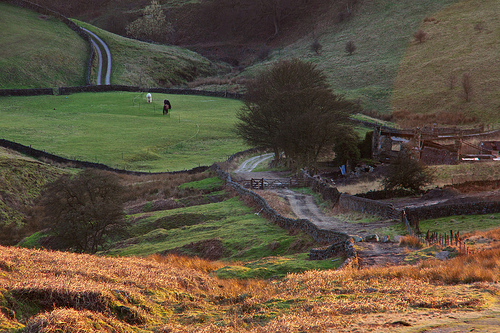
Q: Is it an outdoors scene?
A: Yes, it is outdoors.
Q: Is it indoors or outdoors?
A: It is outdoors.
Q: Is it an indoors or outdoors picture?
A: It is outdoors.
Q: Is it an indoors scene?
A: No, it is outdoors.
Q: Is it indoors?
A: No, it is outdoors.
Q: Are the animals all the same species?
A: Yes, all the animals are horses.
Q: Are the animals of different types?
A: No, all the animals are horses.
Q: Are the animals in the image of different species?
A: No, all the animals are horses.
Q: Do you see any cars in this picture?
A: No, there are no cars.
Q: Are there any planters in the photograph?
A: No, there are no planters.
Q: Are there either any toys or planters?
A: No, there are no planters or toys.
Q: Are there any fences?
A: Yes, there is a fence.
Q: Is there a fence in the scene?
A: Yes, there is a fence.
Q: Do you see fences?
A: Yes, there is a fence.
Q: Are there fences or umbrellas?
A: Yes, there is a fence.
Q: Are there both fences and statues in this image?
A: No, there is a fence but no statues.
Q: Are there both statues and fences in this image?
A: No, there is a fence but no statues.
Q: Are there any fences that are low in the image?
A: Yes, there is a low fence.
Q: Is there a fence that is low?
A: Yes, there is a fence that is low.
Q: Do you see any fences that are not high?
A: Yes, there is a low fence.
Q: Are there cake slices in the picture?
A: No, there are no cake slices.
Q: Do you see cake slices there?
A: No, there are no cake slices.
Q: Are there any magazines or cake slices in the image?
A: No, there are no cake slices or magazines.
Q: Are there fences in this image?
A: Yes, there is a fence.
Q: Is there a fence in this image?
A: Yes, there is a fence.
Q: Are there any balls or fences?
A: Yes, there is a fence.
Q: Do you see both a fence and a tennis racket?
A: No, there is a fence but no rackets.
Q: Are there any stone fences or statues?
A: Yes, there is a stone fence.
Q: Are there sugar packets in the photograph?
A: No, there are no sugar packets.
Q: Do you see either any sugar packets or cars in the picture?
A: No, there are no sugar packets or cars.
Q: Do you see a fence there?
A: Yes, there is a fence.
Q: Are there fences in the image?
A: Yes, there is a fence.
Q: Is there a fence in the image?
A: Yes, there is a fence.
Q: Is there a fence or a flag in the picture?
A: Yes, there is a fence.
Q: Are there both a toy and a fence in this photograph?
A: No, there is a fence but no toys.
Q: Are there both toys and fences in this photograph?
A: No, there is a fence but no toys.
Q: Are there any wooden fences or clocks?
A: Yes, there is a wood fence.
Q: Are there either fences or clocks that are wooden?
A: Yes, the fence is wooden.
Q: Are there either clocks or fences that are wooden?
A: Yes, the fence is wooden.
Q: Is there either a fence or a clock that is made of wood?
A: Yes, the fence is made of wood.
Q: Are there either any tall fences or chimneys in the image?
A: Yes, there is a tall fence.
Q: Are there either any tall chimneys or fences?
A: Yes, there is a tall fence.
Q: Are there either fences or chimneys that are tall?
A: Yes, the fence is tall.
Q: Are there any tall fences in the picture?
A: Yes, there is a tall fence.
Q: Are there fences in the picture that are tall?
A: Yes, there is a fence that is tall.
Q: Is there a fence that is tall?
A: Yes, there is a fence that is tall.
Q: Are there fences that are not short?
A: Yes, there is a tall fence.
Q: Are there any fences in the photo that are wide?
A: Yes, there is a wide fence.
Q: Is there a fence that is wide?
A: Yes, there is a fence that is wide.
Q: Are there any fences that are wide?
A: Yes, there is a fence that is wide.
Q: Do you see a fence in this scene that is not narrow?
A: Yes, there is a wide fence.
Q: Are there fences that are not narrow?
A: Yes, there is a wide fence.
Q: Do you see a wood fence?
A: Yes, there is a wood fence.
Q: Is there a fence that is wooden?
A: Yes, there is a fence that is wooden.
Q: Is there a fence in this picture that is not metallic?
A: Yes, there is a wooden fence.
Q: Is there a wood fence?
A: Yes, there is a fence that is made of wood.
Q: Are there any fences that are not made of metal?
A: Yes, there is a fence that is made of wood.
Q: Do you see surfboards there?
A: No, there are no surfboards.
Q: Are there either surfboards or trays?
A: No, there are no surfboards or trays.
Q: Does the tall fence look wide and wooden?
A: Yes, the fence is wide and wooden.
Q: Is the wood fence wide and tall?
A: Yes, the fence is wide and tall.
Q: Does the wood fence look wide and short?
A: No, the fence is wide but tall.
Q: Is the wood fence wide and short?
A: No, the fence is wide but tall.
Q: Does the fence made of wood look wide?
A: Yes, the fence is wide.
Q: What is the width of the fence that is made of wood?
A: The fence is wide.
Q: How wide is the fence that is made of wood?
A: The fence is wide.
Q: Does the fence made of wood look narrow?
A: No, the fence is wide.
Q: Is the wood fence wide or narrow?
A: The fence is wide.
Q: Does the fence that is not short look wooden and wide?
A: Yes, the fence is wooden and wide.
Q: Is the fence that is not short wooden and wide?
A: Yes, the fence is wooden and wide.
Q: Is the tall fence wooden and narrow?
A: No, the fence is wooden but wide.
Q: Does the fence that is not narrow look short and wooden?
A: No, the fence is wooden but tall.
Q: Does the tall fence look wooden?
A: Yes, the fence is wooden.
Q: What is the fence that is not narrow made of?
A: The fence is made of wood.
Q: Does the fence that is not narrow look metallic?
A: No, the fence is wooden.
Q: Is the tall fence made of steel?
A: No, the fence is made of wood.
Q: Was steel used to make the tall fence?
A: No, the fence is made of wood.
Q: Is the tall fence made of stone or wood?
A: The fence is made of wood.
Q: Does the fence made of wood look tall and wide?
A: Yes, the fence is tall and wide.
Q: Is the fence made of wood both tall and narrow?
A: No, the fence is tall but wide.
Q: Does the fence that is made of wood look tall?
A: Yes, the fence is tall.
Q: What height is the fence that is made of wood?
A: The fence is tall.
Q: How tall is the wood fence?
A: The fence is tall.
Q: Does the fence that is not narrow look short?
A: No, the fence is tall.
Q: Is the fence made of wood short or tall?
A: The fence is tall.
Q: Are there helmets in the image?
A: No, there are no helmets.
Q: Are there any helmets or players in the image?
A: No, there are no helmets or players.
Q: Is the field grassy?
A: Yes, the field is grassy.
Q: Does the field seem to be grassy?
A: Yes, the field is grassy.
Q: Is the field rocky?
A: No, the field is grassy.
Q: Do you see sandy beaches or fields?
A: No, there is a field but it is grassy.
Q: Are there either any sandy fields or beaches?
A: No, there is a field but it is grassy.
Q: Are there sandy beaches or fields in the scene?
A: No, there is a field but it is grassy.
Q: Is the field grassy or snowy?
A: The field is grassy.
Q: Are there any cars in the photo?
A: No, there are no cars.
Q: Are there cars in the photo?
A: No, there are no cars.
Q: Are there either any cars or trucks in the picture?
A: No, there are no cars or trucks.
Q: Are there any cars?
A: No, there are no cars.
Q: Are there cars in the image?
A: No, there are no cars.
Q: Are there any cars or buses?
A: No, there are no cars or buses.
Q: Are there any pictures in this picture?
A: No, there are no pictures.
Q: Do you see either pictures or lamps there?
A: No, there are no pictures or lamps.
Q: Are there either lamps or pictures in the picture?
A: No, there are no pictures or lamps.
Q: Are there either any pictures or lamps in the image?
A: No, there are no pictures or lamps.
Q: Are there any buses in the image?
A: No, there are no buses.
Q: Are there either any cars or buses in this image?
A: No, there are no buses or cars.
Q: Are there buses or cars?
A: No, there are no buses or cars.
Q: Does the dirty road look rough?
A: Yes, the road is rough.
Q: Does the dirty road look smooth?
A: No, the road is rough.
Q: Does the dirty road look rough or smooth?
A: The road is rough.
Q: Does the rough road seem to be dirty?
A: Yes, the road is dirty.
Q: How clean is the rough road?
A: The road is dirty.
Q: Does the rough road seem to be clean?
A: No, the road is dirty.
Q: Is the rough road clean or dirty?
A: The road is dirty.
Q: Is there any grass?
A: Yes, there is grass.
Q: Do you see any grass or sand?
A: Yes, there is grass.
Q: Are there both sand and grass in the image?
A: No, there is grass but no sand.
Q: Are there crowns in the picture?
A: No, there are no crowns.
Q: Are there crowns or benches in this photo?
A: No, there are no crowns or benches.